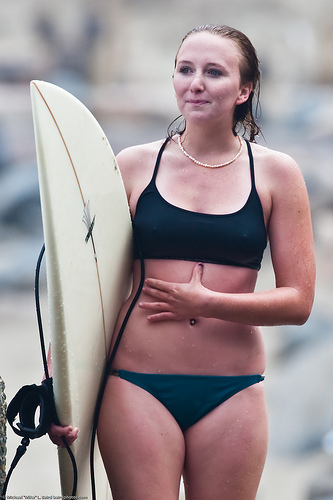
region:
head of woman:
[148, 26, 275, 146]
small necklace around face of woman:
[172, 129, 262, 179]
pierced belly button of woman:
[182, 312, 198, 328]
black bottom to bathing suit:
[104, 366, 263, 430]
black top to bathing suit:
[135, 135, 262, 277]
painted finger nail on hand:
[191, 263, 203, 272]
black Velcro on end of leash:
[0, 381, 43, 441]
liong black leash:
[91, 277, 145, 358]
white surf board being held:
[28, 80, 125, 432]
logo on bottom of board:
[65, 195, 104, 242]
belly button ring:
[188, 318, 195, 326]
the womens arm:
[277, 218, 310, 270]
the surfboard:
[51, 274, 96, 343]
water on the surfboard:
[48, 303, 93, 367]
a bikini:
[155, 387, 205, 404]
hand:
[145, 276, 195, 317]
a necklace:
[204, 160, 216, 169]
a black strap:
[6, 402, 44, 438]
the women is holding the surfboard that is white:
[50, 420, 80, 447]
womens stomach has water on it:
[142, 333, 194, 368]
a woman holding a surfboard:
[13, 5, 318, 492]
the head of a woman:
[160, 19, 263, 128]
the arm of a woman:
[135, 146, 326, 323]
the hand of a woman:
[44, 421, 79, 448]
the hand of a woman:
[136, 260, 216, 332]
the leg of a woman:
[94, 383, 182, 498]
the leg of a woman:
[184, 391, 270, 498]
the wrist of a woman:
[201, 283, 217, 323]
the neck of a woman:
[174, 119, 245, 144]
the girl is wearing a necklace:
[170, 125, 245, 171]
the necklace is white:
[170, 127, 245, 167]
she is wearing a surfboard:
[25, 73, 113, 497]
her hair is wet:
[160, 22, 269, 152]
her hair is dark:
[157, 19, 275, 151]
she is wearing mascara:
[176, 62, 193, 74]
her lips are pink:
[186, 99, 210, 107]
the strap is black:
[5, 226, 151, 494]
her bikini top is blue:
[128, 126, 271, 270]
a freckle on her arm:
[296, 209, 301, 215]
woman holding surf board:
[103, 33, 271, 373]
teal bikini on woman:
[114, 356, 274, 421]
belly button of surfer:
[182, 315, 200, 333]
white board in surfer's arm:
[26, 76, 117, 415]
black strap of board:
[117, 263, 153, 335]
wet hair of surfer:
[178, 15, 265, 47]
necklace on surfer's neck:
[172, 132, 251, 173]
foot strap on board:
[7, 370, 58, 447]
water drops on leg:
[216, 433, 245, 499]